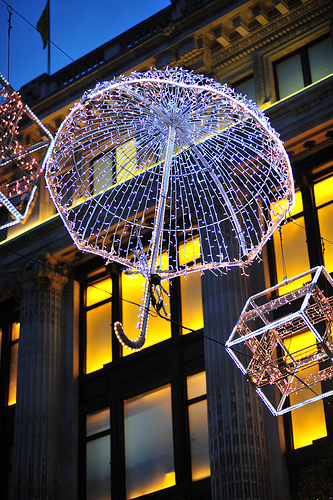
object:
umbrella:
[44, 66, 297, 350]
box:
[224, 263, 333, 415]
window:
[77, 272, 120, 374]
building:
[2, 0, 331, 499]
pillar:
[11, 250, 69, 500]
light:
[52, 26, 167, 90]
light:
[2, 85, 46, 200]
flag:
[37, 0, 52, 81]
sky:
[0, 0, 171, 103]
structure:
[0, 67, 53, 230]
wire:
[2, 242, 332, 422]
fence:
[1, 2, 174, 110]